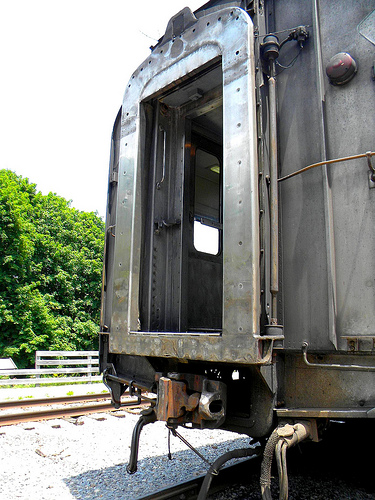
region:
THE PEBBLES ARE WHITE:
[66, 442, 94, 466]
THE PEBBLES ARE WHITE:
[76, 436, 87, 446]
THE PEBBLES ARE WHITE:
[87, 437, 100, 449]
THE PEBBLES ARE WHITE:
[94, 469, 115, 484]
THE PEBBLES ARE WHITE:
[81, 445, 92, 458]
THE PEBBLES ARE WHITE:
[90, 424, 106, 453]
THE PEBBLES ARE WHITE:
[90, 464, 108, 474]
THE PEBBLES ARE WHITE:
[87, 488, 103, 493]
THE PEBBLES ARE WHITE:
[99, 449, 119, 470]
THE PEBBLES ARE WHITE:
[35, 450, 70, 470]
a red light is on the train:
[323, 49, 362, 90]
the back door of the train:
[94, 2, 268, 371]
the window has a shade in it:
[185, 140, 228, 263]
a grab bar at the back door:
[157, 109, 172, 196]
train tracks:
[15, 389, 132, 437]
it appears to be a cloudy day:
[42, 65, 93, 152]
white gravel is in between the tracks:
[39, 460, 110, 492]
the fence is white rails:
[27, 335, 105, 387]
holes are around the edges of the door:
[117, 10, 275, 154]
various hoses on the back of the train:
[199, 423, 327, 497]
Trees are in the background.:
[5, 188, 97, 338]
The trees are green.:
[3, 199, 91, 333]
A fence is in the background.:
[2, 346, 95, 383]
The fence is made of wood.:
[2, 347, 93, 383]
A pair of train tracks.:
[3, 385, 91, 428]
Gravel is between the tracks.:
[26, 444, 112, 493]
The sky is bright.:
[12, 54, 93, 142]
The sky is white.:
[13, 38, 95, 144]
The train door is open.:
[127, 50, 242, 340]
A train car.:
[91, 0, 372, 496]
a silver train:
[79, 4, 374, 357]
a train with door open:
[100, 23, 319, 462]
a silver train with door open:
[59, 59, 305, 391]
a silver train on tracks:
[102, 136, 353, 499]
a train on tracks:
[86, 178, 335, 499]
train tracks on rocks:
[1, 374, 139, 463]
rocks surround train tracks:
[26, 380, 125, 476]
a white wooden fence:
[29, 351, 95, 385]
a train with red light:
[295, 16, 374, 107]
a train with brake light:
[289, 35, 367, 108]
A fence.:
[3, 343, 98, 379]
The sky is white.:
[20, 33, 82, 109]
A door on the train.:
[135, 46, 249, 350]